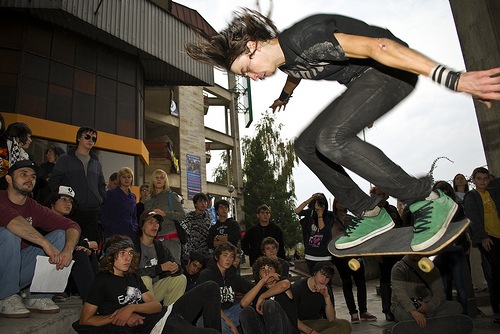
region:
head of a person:
[193, 4, 293, 89]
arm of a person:
[330, 7, 497, 103]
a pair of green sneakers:
[332, 171, 457, 253]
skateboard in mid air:
[314, 213, 476, 272]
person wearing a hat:
[74, 234, 161, 331]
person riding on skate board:
[200, 8, 497, 293]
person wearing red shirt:
[2, 163, 99, 308]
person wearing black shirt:
[202, 0, 497, 248]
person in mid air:
[208, 0, 498, 253]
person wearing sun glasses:
[36, 105, 119, 245]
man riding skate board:
[194, 7, 485, 276]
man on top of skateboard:
[198, 0, 468, 270]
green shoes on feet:
[401, 187, 458, 246]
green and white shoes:
[403, 191, 467, 246]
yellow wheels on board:
[416, 249, 438, 268]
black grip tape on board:
[371, 230, 418, 252]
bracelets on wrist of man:
[431, 60, 463, 94]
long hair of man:
[218, 0, 282, 36]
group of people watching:
[0, 129, 249, 299]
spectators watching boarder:
[0, 138, 259, 315]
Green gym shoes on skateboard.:
[340, 196, 456, 258]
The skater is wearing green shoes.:
[208, 15, 449, 240]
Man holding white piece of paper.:
[7, 165, 74, 308]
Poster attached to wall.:
[175, 136, 219, 203]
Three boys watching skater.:
[216, 247, 343, 305]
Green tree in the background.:
[250, 125, 298, 227]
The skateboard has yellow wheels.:
[330, 252, 442, 286]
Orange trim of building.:
[75, 126, 170, 163]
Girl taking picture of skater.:
[303, 190, 328, 248]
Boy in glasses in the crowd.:
[67, 121, 108, 186]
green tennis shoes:
[332, 188, 459, 250]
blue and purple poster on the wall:
[183, 151, 200, 198]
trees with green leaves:
[203, 105, 301, 247]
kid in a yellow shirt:
[457, 165, 497, 318]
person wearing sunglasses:
[43, 123, 99, 248]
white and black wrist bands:
[428, 63, 460, 92]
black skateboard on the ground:
[389, 313, 473, 333]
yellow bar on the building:
[1, 112, 150, 164]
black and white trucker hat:
[48, 184, 75, 199]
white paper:
[30, 253, 74, 293]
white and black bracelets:
[431, 65, 460, 90]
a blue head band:
[104, 239, 132, 256]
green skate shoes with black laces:
[334, 190, 454, 249]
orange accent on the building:
[5, 112, 151, 162]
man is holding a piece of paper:
[26, 243, 74, 295]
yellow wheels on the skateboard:
[347, 258, 434, 270]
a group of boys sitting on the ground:
[96, 209, 342, 327]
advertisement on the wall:
[183, 153, 202, 200]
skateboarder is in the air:
[187, 10, 494, 272]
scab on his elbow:
[375, 42, 385, 49]